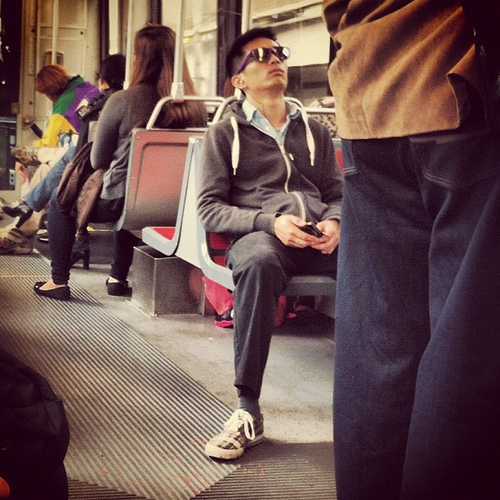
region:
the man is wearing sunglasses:
[196, 29, 361, 474]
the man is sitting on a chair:
[188, 37, 341, 419]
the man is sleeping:
[203, 19, 385, 476]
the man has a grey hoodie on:
[200, 21, 375, 478]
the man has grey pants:
[184, 24, 398, 490]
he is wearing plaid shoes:
[184, 394, 285, 465]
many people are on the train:
[13, 10, 472, 492]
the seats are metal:
[18, 28, 284, 308]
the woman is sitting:
[64, 22, 194, 315]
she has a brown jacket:
[65, 19, 175, 297]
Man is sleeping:
[212, 24, 329, 186]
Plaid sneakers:
[198, 398, 272, 462]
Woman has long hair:
[130, 17, 202, 127]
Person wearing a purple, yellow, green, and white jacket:
[33, 82, 99, 163]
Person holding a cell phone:
[259, 214, 354, 259]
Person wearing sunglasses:
[252, 43, 292, 66]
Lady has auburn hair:
[130, 22, 204, 127]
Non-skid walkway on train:
[3, 300, 239, 494]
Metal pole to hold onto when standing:
[169, 2, 191, 99]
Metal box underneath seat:
[131, 245, 186, 321]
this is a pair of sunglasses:
[229, 38, 294, 78]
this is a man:
[192, 36, 344, 440]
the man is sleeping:
[224, 35, 311, 130]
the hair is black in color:
[248, 30, 275, 40]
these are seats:
[138, 127, 201, 259]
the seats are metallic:
[138, 130, 189, 227]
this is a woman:
[48, 35, 183, 300]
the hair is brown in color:
[148, 38, 164, 67]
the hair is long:
[143, 30, 206, 127]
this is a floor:
[47, 342, 146, 404]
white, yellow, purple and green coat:
[34, 74, 107, 155]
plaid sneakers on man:
[205, 408, 264, 460]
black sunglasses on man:
[235, 45, 292, 75]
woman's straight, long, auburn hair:
[128, 23, 205, 135]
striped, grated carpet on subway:
[27, 297, 177, 477]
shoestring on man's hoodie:
[224, 110, 244, 177]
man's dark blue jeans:
[328, 66, 495, 496]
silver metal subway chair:
[120, 80, 227, 247]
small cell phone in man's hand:
[297, 220, 325, 240]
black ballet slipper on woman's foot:
[28, 279, 72, 299]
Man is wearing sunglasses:
[207, 19, 317, 86]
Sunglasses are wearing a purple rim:
[216, 12, 297, 104]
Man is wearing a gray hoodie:
[191, 89, 359, 262]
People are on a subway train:
[8, 5, 498, 499]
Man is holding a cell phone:
[285, 199, 338, 266]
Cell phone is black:
[273, 209, 334, 260]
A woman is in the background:
[20, 16, 212, 306]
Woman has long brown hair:
[123, 14, 215, 151]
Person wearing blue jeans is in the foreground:
[308, 106, 498, 497]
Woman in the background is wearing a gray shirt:
[77, 83, 215, 221]